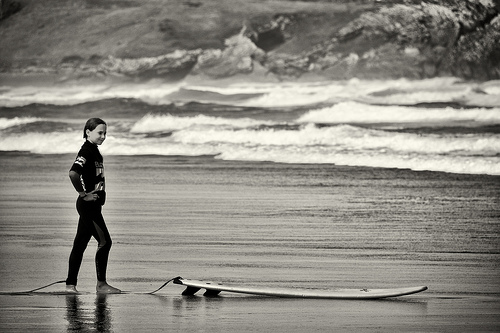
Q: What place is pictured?
A: It is a shore.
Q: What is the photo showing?
A: It is showing a shore.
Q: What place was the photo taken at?
A: It was taken at the shore.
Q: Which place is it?
A: It is a shore.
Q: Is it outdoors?
A: Yes, it is outdoors.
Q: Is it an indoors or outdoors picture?
A: It is outdoors.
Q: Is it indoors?
A: No, it is outdoors.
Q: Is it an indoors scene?
A: No, it is outdoors.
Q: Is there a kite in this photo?
A: No, there are no kites.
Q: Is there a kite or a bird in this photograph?
A: No, there are no kites or birds.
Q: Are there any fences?
A: No, there are no fences.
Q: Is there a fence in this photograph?
A: No, there are no fences.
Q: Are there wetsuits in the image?
A: Yes, there is a wetsuit.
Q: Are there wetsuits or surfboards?
A: Yes, there is a wetsuit.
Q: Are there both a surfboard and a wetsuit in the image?
A: Yes, there are both a wetsuit and a surfboard.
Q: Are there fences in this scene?
A: No, there are no fences.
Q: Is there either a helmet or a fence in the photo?
A: No, there are no fences or helmets.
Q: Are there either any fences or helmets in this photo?
A: No, there are no fences or helmets.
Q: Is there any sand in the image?
A: Yes, there is sand.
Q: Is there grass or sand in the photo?
A: Yes, there is sand.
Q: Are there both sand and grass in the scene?
A: No, there is sand but no grass.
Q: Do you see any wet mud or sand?
A: Yes, there is wet sand.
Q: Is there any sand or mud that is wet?
A: Yes, the sand is wet.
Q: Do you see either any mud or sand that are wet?
A: Yes, the sand is wet.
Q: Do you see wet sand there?
A: Yes, there is wet sand.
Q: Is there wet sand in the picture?
A: Yes, there is wet sand.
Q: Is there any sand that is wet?
A: Yes, there is sand that is wet.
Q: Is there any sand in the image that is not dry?
A: Yes, there is wet sand.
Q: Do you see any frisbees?
A: No, there are no frisbees.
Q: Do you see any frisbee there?
A: No, there are no frisbees.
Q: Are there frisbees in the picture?
A: No, there are no frisbees.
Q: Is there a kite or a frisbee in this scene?
A: No, there are no frisbees or kites.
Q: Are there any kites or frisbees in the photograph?
A: No, there are no frisbees or kites.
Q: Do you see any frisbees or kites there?
A: No, there are no frisbees or kites.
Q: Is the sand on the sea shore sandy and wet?
A: Yes, the sand is sandy and wet.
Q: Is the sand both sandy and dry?
A: No, the sand is sandy but wet.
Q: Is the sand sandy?
A: Yes, the sand is sandy.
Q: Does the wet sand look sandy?
A: Yes, the sand is sandy.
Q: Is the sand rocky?
A: No, the sand is sandy.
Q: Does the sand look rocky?
A: No, the sand is sandy.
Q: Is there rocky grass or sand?
A: No, there is sand but it is sandy.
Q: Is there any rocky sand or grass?
A: No, there is sand but it is sandy.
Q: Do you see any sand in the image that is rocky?
A: No, there is sand but it is sandy.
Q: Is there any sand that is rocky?
A: No, there is sand but it is sandy.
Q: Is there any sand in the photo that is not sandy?
A: No, there is sand but it is sandy.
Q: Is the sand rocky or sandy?
A: The sand is sandy.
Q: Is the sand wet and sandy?
A: Yes, the sand is wet and sandy.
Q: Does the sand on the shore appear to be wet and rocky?
A: No, the sand is wet but sandy.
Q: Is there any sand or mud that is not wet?
A: No, there is sand but it is wet.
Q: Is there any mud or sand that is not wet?
A: No, there is sand but it is wet.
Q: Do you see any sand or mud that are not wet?
A: No, there is sand but it is wet.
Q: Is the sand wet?
A: Yes, the sand is wet.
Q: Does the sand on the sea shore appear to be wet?
A: Yes, the sand is wet.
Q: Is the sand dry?
A: No, the sand is wet.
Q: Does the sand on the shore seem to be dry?
A: No, the sand is wet.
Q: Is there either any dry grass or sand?
A: No, there is sand but it is wet.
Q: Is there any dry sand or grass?
A: No, there is sand but it is wet.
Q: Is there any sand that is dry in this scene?
A: No, there is sand but it is wet.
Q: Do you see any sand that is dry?
A: No, there is sand but it is wet.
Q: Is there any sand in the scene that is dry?
A: No, there is sand but it is wet.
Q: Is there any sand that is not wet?
A: No, there is sand but it is wet.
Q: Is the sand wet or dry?
A: The sand is wet.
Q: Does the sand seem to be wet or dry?
A: The sand is wet.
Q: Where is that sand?
A: The sand is on the shore.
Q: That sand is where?
A: The sand is on the shore.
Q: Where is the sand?
A: The sand is on the shore.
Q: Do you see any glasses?
A: No, there are no glasses.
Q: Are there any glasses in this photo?
A: No, there are no glasses.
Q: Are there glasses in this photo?
A: No, there are no glasses.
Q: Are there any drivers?
A: No, there are no drivers.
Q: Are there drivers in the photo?
A: No, there are no drivers.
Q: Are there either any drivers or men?
A: No, there are no drivers or men.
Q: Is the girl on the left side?
A: Yes, the girl is on the left of the image.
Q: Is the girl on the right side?
A: No, the girl is on the left of the image.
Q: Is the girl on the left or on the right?
A: The girl is on the left of the image.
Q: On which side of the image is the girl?
A: The girl is on the left of the image.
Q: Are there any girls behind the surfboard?
A: Yes, there is a girl behind the surfboard.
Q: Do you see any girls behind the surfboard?
A: Yes, there is a girl behind the surfboard.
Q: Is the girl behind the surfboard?
A: Yes, the girl is behind the surfboard.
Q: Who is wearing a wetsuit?
A: The girl is wearing a wetsuit.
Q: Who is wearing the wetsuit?
A: The girl is wearing a wetsuit.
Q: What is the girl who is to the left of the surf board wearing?
A: The girl is wearing a wetsuit.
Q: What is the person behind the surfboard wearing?
A: The girl is wearing a wetsuit.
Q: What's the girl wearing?
A: The girl is wearing a wetsuit.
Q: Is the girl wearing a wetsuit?
A: Yes, the girl is wearing a wetsuit.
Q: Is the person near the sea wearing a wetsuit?
A: Yes, the girl is wearing a wetsuit.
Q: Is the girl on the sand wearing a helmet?
A: No, the girl is wearing a wetsuit.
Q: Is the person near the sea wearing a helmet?
A: No, the girl is wearing a wetsuit.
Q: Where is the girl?
A: The girl is on the sand.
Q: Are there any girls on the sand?
A: Yes, there is a girl on the sand.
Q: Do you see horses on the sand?
A: No, there is a girl on the sand.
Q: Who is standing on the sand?
A: The girl is standing on the sand.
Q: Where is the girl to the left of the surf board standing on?
A: The girl is standing on the sand.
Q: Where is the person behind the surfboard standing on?
A: The girl is standing on the sand.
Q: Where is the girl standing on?
A: The girl is standing on the sand.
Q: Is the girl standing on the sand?
A: Yes, the girl is standing on the sand.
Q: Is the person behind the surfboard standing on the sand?
A: Yes, the girl is standing on the sand.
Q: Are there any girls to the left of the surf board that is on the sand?
A: Yes, there is a girl to the left of the surfboard.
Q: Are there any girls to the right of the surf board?
A: No, the girl is to the left of the surf board.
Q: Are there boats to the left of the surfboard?
A: No, there is a girl to the left of the surfboard.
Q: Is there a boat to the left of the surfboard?
A: No, there is a girl to the left of the surfboard.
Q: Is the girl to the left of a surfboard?
A: Yes, the girl is to the left of a surfboard.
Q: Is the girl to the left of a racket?
A: No, the girl is to the left of a surfboard.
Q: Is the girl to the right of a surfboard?
A: No, the girl is to the left of a surfboard.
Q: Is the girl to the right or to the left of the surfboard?
A: The girl is to the left of the surfboard.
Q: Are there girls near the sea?
A: Yes, there is a girl near the sea.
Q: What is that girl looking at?
A: The girl is looking at the sea.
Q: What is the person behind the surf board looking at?
A: The girl is looking at the sea.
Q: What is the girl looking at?
A: The girl is looking at the sea.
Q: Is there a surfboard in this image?
A: Yes, there is a surfboard.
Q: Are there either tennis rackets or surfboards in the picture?
A: Yes, there is a surfboard.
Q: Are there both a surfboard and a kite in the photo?
A: No, there is a surfboard but no kites.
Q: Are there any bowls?
A: No, there are no bowls.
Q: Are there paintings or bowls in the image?
A: No, there are no bowls or paintings.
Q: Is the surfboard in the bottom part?
A: Yes, the surfboard is in the bottom of the image.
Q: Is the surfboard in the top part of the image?
A: No, the surfboard is in the bottom of the image.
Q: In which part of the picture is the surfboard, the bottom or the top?
A: The surfboard is in the bottom of the image.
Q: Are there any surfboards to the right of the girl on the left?
A: Yes, there is a surfboard to the right of the girl.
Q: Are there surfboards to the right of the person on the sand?
A: Yes, there is a surfboard to the right of the girl.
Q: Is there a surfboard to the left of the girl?
A: No, the surfboard is to the right of the girl.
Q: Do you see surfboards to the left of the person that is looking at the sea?
A: No, the surfboard is to the right of the girl.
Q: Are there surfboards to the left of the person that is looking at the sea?
A: No, the surfboard is to the right of the girl.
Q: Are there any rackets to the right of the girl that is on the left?
A: No, there is a surfboard to the right of the girl.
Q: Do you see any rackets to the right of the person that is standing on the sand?
A: No, there is a surfboard to the right of the girl.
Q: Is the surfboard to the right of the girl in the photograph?
A: Yes, the surfboard is to the right of the girl.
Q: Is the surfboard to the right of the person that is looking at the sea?
A: Yes, the surfboard is to the right of the girl.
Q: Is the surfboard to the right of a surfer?
A: No, the surfboard is to the right of the girl.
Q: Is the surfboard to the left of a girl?
A: No, the surfboard is to the right of a girl.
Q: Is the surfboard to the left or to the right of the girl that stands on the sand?
A: The surfboard is to the right of the girl.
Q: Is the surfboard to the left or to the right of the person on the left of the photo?
A: The surfboard is to the right of the girl.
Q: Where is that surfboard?
A: The surfboard is on the sand.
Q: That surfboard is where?
A: The surfboard is on the sand.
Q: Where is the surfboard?
A: The surfboard is on the sand.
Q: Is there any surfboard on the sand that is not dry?
A: Yes, there is a surfboard on the sand.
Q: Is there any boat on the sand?
A: No, there is a surfboard on the sand.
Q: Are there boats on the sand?
A: No, there is a surfboard on the sand.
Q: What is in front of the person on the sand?
A: The surfboard is in front of the girl.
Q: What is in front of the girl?
A: The surfboard is in front of the girl.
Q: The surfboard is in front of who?
A: The surfboard is in front of the girl.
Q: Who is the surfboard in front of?
A: The surfboard is in front of the girl.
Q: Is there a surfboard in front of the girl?
A: Yes, there is a surfboard in front of the girl.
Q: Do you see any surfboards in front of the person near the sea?
A: Yes, there is a surfboard in front of the girl.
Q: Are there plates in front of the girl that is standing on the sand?
A: No, there is a surfboard in front of the girl.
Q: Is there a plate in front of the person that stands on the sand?
A: No, there is a surfboard in front of the girl.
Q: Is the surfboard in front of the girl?
A: Yes, the surfboard is in front of the girl.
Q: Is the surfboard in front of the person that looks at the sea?
A: Yes, the surfboard is in front of the girl.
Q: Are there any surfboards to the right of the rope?
A: Yes, there is a surfboard to the right of the rope.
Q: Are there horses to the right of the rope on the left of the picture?
A: No, there is a surfboard to the right of the rope.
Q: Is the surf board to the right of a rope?
A: Yes, the surf board is to the right of a rope.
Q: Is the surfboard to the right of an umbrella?
A: No, the surfboard is to the right of a rope.